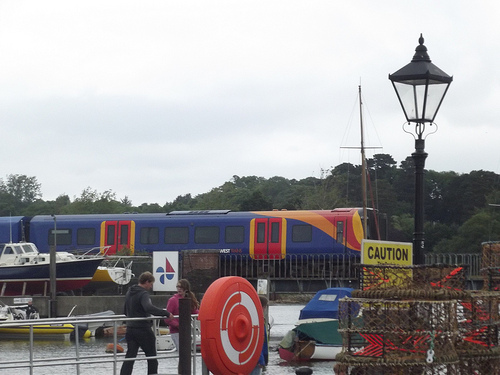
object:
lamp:
[387, 28, 457, 123]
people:
[119, 270, 200, 375]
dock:
[0, 302, 357, 375]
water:
[0, 306, 305, 375]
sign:
[359, 239, 413, 265]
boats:
[279, 287, 355, 359]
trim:
[336, 208, 364, 251]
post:
[411, 141, 427, 266]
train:
[0, 211, 389, 279]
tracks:
[0, 276, 368, 375]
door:
[253, 219, 282, 260]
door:
[104, 221, 129, 251]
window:
[161, 227, 189, 244]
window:
[289, 222, 312, 242]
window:
[77, 228, 94, 245]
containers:
[333, 240, 496, 374]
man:
[119, 271, 172, 375]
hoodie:
[121, 284, 169, 327]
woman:
[166, 279, 199, 353]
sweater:
[164, 293, 200, 334]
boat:
[0, 242, 107, 296]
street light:
[387, 31, 454, 264]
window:
[46, 229, 72, 246]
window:
[105, 223, 115, 246]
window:
[121, 223, 127, 246]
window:
[137, 225, 157, 245]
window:
[193, 222, 221, 245]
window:
[224, 224, 247, 245]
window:
[256, 223, 264, 243]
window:
[271, 221, 279, 242]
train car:
[27, 209, 369, 266]